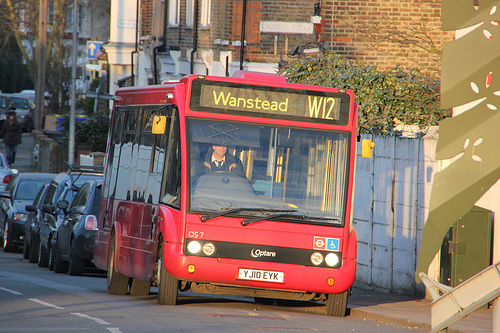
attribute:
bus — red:
[93, 70, 356, 312]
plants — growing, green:
[286, 54, 448, 133]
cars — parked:
[0, 151, 100, 278]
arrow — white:
[87, 42, 98, 59]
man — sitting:
[197, 144, 248, 176]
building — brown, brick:
[136, 3, 457, 78]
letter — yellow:
[213, 89, 341, 123]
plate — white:
[240, 268, 285, 283]